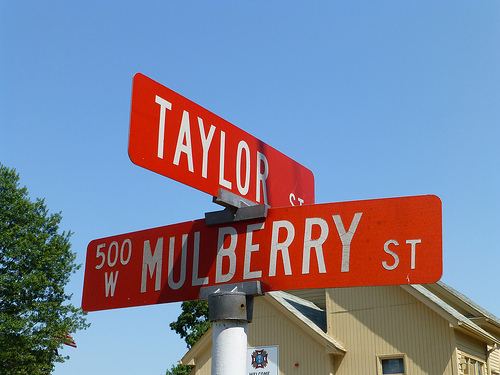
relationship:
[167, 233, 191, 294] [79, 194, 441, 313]
letter on a sign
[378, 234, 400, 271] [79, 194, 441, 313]
letter on a sign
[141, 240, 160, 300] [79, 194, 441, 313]
letter on a sign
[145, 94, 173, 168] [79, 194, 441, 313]
letter on a sign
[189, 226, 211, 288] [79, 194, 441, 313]
letter on a sign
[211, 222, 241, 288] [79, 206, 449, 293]
letter on a sign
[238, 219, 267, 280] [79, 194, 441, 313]
letter on a sign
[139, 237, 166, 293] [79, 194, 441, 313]
letter on sign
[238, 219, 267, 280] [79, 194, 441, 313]
letter on sign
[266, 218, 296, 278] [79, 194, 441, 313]
letter on sign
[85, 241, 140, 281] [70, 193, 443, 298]
number 500 on sign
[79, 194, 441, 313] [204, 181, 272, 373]
sign on pole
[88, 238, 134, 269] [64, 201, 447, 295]
number 500 on sign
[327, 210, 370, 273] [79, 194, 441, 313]
letter on sign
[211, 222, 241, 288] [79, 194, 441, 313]
letter on sign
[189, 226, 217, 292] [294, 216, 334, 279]
letter on sign